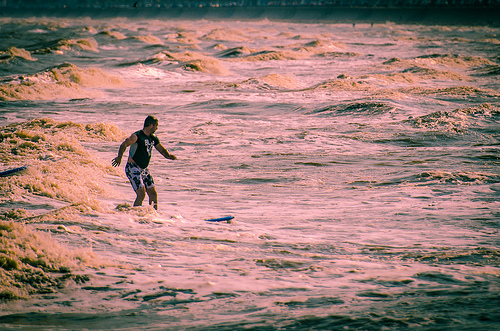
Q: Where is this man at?
A: A beach.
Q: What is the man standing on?
A: A surfboard.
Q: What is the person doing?
A: Surfing.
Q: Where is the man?
A: At the beach.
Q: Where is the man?
A: In the water.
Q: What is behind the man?
A: A wave.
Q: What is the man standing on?
A: A surfboard.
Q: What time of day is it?
A: Evening.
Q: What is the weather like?
A: Warm.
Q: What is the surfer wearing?
A: Swim trunks.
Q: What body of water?
A: Ocean.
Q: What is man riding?
A: Surfboard.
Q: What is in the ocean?
A: Surfboard.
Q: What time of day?
A: Sunset.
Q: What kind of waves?
A: Choppy.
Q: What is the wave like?
A: Calm.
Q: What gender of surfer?
A: Male.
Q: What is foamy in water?
A: Waves.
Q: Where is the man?
A: In ocean.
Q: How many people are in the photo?
A: One.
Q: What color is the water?
A: Blue.